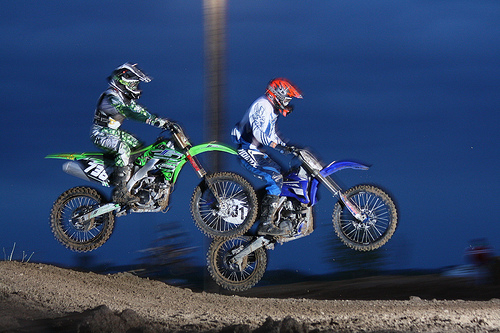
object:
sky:
[0, 1, 500, 271]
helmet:
[265, 76, 304, 118]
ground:
[0, 257, 498, 332]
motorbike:
[203, 144, 400, 293]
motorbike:
[44, 119, 258, 253]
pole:
[200, 0, 229, 297]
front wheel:
[330, 181, 400, 252]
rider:
[228, 76, 303, 238]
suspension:
[313, 168, 366, 224]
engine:
[269, 197, 312, 242]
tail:
[54, 161, 88, 181]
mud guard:
[308, 159, 371, 209]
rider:
[86, 61, 180, 204]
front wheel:
[188, 169, 258, 242]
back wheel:
[202, 230, 268, 293]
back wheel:
[49, 187, 115, 254]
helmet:
[103, 62, 152, 101]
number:
[217, 199, 249, 225]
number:
[80, 157, 114, 183]